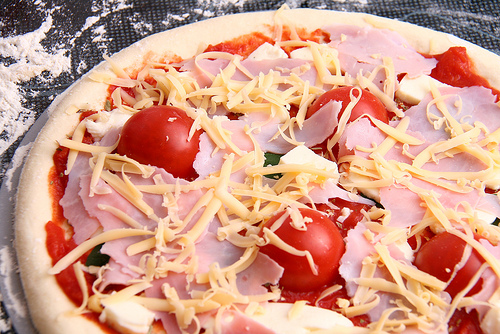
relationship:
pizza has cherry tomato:
[10, 3, 499, 328] [112, 98, 209, 179]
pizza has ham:
[10, 3, 499, 328] [340, 24, 442, 77]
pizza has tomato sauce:
[10, 3, 499, 328] [430, 47, 479, 89]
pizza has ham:
[10, 3, 499, 328] [387, 87, 499, 176]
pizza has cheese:
[10, 3, 499, 328] [281, 141, 340, 176]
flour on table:
[0, 16, 70, 99] [4, 1, 113, 64]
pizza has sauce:
[10, 3, 499, 328] [44, 219, 95, 301]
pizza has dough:
[10, 3, 499, 328] [11, 101, 60, 326]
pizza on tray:
[10, 3, 499, 328] [4, 79, 41, 332]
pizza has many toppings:
[10, 3, 499, 328] [59, 26, 499, 328]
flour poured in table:
[0, 16, 70, 99] [4, 1, 113, 64]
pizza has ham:
[10, 3, 499, 328] [80, 173, 205, 269]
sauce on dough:
[44, 219, 95, 301] [11, 101, 60, 326]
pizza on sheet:
[10, 3, 499, 328] [2, 81, 25, 328]